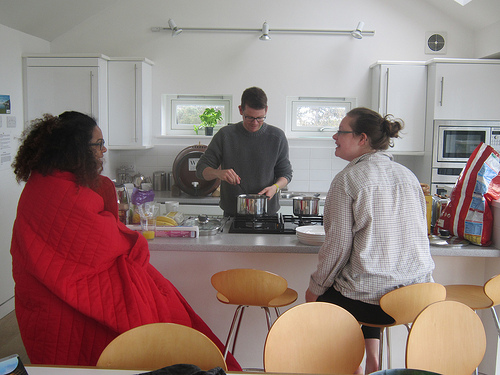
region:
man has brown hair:
[247, 91, 268, 114]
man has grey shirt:
[180, 118, 285, 214]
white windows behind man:
[169, 75, 347, 139]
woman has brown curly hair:
[10, 91, 138, 229]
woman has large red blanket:
[22, 184, 217, 369]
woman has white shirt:
[327, 151, 448, 301]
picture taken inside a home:
[43, 29, 468, 371]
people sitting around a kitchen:
[15, 16, 485, 324]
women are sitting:
[19, 56, 471, 306]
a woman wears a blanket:
[28, 144, 220, 365]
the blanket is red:
[47, 173, 160, 318]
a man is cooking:
[180, 63, 300, 227]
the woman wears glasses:
[82, 129, 112, 159]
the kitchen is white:
[58, 24, 488, 60]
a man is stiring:
[228, 163, 311, 232]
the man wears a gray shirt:
[247, 147, 262, 166]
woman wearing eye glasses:
[320, 101, 411, 169]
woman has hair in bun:
[321, 101, 424, 167]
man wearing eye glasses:
[219, 78, 288, 153]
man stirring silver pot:
[178, 89, 298, 233]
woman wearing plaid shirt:
[310, 153, 441, 294]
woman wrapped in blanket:
[2, 101, 207, 372]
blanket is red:
[5, 149, 211, 357]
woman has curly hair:
[6, 98, 134, 200]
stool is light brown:
[186, 245, 301, 357]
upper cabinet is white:
[17, 40, 167, 155]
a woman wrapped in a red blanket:
[8, 110, 235, 367]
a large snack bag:
[435, 141, 499, 246]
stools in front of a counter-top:
[137, 231, 498, 368]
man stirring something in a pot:
[197, 86, 292, 221]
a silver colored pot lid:
[181, 212, 222, 236]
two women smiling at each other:
[11, 104, 434, 374]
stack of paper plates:
[294, 221, 324, 248]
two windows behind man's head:
[160, 85, 352, 130]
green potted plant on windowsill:
[160, 93, 231, 138]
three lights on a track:
[151, 17, 376, 47]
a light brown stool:
[266, 300, 364, 371]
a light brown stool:
[408, 300, 486, 372]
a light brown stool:
[94, 322, 227, 372]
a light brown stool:
[206, 268, 296, 308]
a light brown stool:
[359, 283, 446, 330]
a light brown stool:
[442, 275, 497, 310]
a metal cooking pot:
[236, 192, 270, 217]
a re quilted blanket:
[9, 170, 239, 367]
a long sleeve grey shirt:
[194, 120, 293, 215]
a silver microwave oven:
[439, 125, 498, 161]